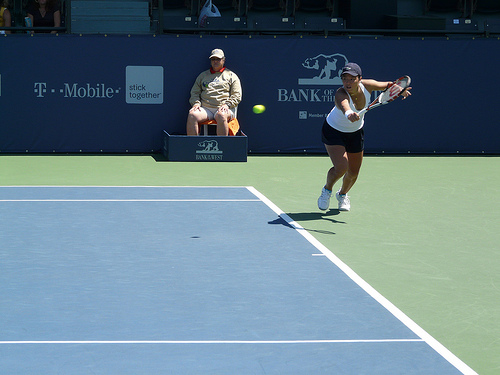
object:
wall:
[1, 34, 499, 154]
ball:
[252, 104, 265, 114]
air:
[428, 184, 493, 239]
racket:
[357, 74, 410, 119]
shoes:
[315, 188, 332, 211]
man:
[187, 48, 242, 136]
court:
[2, 152, 499, 373]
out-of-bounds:
[0, 154, 498, 185]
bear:
[302, 53, 349, 80]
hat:
[341, 62, 362, 77]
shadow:
[269, 208, 345, 235]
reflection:
[190, 234, 202, 240]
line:
[1, 184, 253, 190]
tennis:
[253, 63, 412, 210]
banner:
[34, 82, 119, 100]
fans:
[22, 1, 64, 34]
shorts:
[322, 116, 364, 153]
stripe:
[1, 184, 254, 190]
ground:
[0, 154, 500, 375]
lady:
[320, 63, 411, 211]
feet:
[318, 187, 332, 211]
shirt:
[324, 82, 371, 133]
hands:
[348, 112, 361, 122]